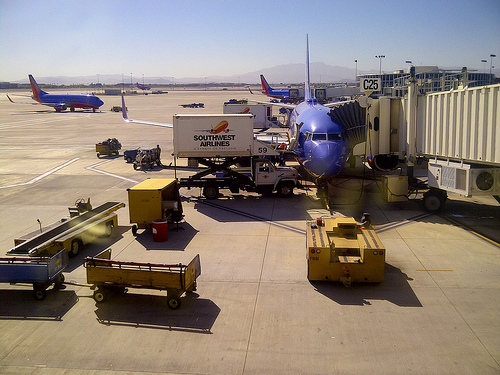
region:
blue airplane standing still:
[289, 39, 346, 181]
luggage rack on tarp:
[128, 177, 197, 239]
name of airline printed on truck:
[163, 128, 247, 149]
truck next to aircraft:
[178, 104, 300, 204]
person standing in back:
[128, 145, 164, 174]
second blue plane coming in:
[33, 87, 102, 127]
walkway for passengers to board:
[346, 91, 498, 166]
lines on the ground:
[1, 154, 136, 186]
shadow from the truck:
[98, 295, 191, 327]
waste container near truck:
[146, 218, 176, 252]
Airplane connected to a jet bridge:
[255, 28, 352, 183]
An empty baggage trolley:
[0, 250, 220, 313]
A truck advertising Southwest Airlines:
[167, 110, 297, 203]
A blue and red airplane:
[5, 70, 107, 117]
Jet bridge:
[333, 78, 493, 220]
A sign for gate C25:
[355, 72, 384, 95]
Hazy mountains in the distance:
[0, 58, 495, 91]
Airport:
[322, 52, 494, 96]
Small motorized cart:
[85, 133, 123, 159]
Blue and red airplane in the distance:
[133, 79, 155, 94]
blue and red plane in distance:
[25, 63, 109, 118]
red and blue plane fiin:
[23, 73, 45, 95]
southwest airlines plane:
[20, 66, 109, 121]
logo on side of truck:
[197, 118, 234, 154]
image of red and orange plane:
[197, 117, 235, 137]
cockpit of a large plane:
[298, 118, 342, 180]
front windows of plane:
[305, 129, 342, 140]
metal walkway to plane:
[357, 89, 492, 153]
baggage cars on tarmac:
[94, 133, 160, 170]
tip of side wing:
[109, 89, 137, 121]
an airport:
[4, 53, 499, 355]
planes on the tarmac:
[9, 27, 389, 190]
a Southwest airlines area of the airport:
[6, 32, 386, 207]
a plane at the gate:
[120, 23, 497, 220]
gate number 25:
[353, 68, 499, 210]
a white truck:
[172, 107, 279, 178]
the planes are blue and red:
[6, 29, 374, 209]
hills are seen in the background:
[17, 52, 446, 87]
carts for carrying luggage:
[3, 246, 221, 308]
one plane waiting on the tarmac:
[6, 75, 106, 122]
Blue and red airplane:
[12, 58, 120, 136]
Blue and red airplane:
[242, 69, 311, 98]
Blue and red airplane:
[265, 73, 356, 186]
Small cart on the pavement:
[78, 239, 212, 316]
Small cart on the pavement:
[301, 197, 403, 306]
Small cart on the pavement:
[0, 238, 83, 303]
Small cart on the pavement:
[17, 190, 118, 249]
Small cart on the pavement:
[118, 153, 197, 257]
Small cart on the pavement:
[90, 123, 125, 158]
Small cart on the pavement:
[118, 130, 162, 166]